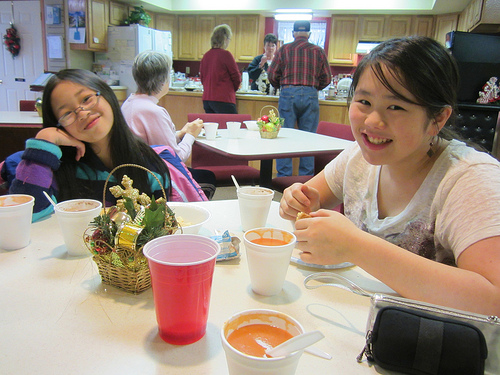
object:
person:
[201, 23, 242, 113]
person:
[249, 34, 278, 96]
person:
[268, 21, 331, 179]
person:
[121, 51, 202, 160]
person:
[279, 36, 499, 318]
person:
[8, 70, 170, 223]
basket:
[87, 163, 178, 292]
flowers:
[96, 248, 101, 251]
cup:
[143, 233, 221, 344]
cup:
[243, 227, 296, 296]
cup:
[1, 192, 35, 250]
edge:
[224, 148, 343, 159]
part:
[293, 138, 306, 147]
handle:
[0, 80, 3, 85]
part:
[1, 80, 3, 82]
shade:
[237, 15, 259, 33]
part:
[283, 28, 287, 33]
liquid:
[238, 325, 275, 343]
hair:
[348, 37, 499, 156]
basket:
[258, 104, 282, 139]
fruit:
[262, 115, 269, 121]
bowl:
[164, 206, 209, 234]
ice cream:
[174, 219, 186, 225]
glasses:
[55, 90, 101, 127]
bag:
[365, 307, 487, 373]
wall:
[172, 12, 197, 69]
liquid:
[257, 239, 281, 244]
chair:
[188, 113, 260, 186]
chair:
[274, 121, 356, 188]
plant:
[125, 4, 150, 26]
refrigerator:
[104, 25, 172, 95]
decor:
[2, 23, 20, 57]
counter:
[188, 114, 358, 161]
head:
[38, 68, 115, 141]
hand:
[36, 127, 86, 159]